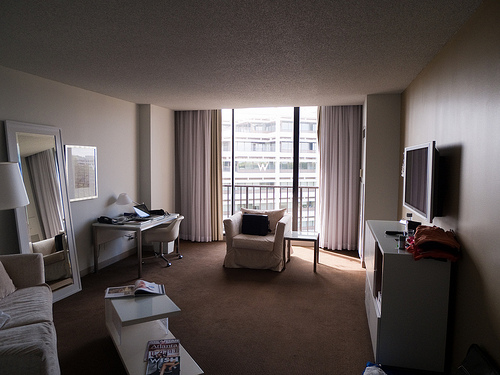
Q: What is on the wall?
A: Mirror.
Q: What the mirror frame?
A: White.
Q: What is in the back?
A: Door.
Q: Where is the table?
A: In front of the sofa.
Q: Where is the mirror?
A: Against the wall.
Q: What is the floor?
A: Carpet.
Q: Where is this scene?
A: In the living room.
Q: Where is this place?
A: Next to the other apartments.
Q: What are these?
A: White furniture.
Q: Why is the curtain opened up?
A: To brighten up the room.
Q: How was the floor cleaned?
A: With a vacuum cleaner.